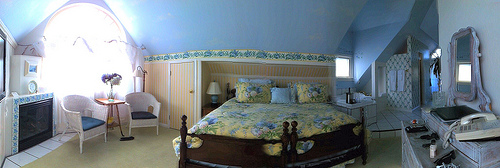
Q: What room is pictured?
A: It is a bedroom.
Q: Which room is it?
A: It is a bedroom.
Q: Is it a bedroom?
A: Yes, it is a bedroom.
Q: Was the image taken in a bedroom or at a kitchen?
A: It was taken at a bedroom.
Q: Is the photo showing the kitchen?
A: No, the picture is showing the bedroom.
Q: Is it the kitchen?
A: No, it is the bedroom.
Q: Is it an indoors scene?
A: Yes, it is indoors.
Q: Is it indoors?
A: Yes, it is indoors.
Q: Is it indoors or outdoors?
A: It is indoors.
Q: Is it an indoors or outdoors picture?
A: It is indoors.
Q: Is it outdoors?
A: No, it is indoors.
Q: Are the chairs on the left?
A: Yes, the chairs are on the left of the image.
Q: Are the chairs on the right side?
A: No, the chairs are on the left of the image.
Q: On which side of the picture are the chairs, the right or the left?
A: The chairs are on the left of the image.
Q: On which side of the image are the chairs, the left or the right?
A: The chairs are on the left of the image.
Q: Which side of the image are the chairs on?
A: The chairs are on the left of the image.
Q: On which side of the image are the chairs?
A: The chairs are on the left of the image.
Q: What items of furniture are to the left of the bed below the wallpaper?
A: The pieces of furniture are chairs.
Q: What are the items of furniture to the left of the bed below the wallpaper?
A: The pieces of furniture are chairs.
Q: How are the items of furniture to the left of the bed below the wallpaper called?
A: The pieces of furniture are chairs.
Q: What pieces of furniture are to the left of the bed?
A: The pieces of furniture are chairs.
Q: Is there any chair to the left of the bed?
A: Yes, there are chairs to the left of the bed.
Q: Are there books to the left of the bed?
A: No, there are chairs to the left of the bed.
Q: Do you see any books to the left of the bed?
A: No, there are chairs to the left of the bed.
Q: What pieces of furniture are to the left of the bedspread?
A: The pieces of furniture are chairs.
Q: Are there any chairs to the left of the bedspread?
A: Yes, there are chairs to the left of the bedspread.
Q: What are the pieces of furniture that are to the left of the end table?
A: The pieces of furniture are chairs.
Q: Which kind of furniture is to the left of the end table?
A: The pieces of furniture are chairs.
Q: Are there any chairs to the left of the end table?
A: Yes, there are chairs to the left of the end table.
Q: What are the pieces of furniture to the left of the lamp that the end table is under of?
A: The pieces of furniture are chairs.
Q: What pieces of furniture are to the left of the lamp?
A: The pieces of furniture are chairs.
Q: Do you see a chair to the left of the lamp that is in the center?
A: Yes, there are chairs to the left of the lamp.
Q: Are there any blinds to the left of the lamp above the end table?
A: No, there are chairs to the left of the lamp.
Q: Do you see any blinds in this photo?
A: No, there are no blinds.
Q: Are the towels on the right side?
A: Yes, the towels are on the right of the image.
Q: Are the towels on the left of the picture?
A: No, the towels are on the right of the image.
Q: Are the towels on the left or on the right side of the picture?
A: The towels are on the right of the image.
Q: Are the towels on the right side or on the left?
A: The towels are on the right of the image.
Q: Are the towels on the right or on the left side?
A: The towels are on the right of the image.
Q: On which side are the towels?
A: The towels are on the right of the image.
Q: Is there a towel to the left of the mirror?
A: Yes, there are towels to the left of the mirror.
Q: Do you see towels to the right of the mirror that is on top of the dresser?
A: No, the towels are to the left of the mirror.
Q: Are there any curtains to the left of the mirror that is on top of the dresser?
A: No, there are towels to the left of the mirror.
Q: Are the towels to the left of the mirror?
A: Yes, the towels are to the left of the mirror.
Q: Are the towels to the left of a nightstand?
A: No, the towels are to the left of the mirror.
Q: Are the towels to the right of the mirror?
A: No, the towels are to the left of the mirror.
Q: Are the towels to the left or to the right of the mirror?
A: The towels are to the left of the mirror.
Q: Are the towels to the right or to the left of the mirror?
A: The towels are to the left of the mirror.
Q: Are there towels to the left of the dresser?
A: Yes, there are towels to the left of the dresser.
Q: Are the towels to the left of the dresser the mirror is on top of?
A: Yes, the towels are to the left of the dresser.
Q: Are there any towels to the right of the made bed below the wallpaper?
A: Yes, there are towels to the right of the bed.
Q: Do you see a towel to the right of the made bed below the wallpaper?
A: Yes, there are towels to the right of the bed.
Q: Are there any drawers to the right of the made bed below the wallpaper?
A: No, there are towels to the right of the bed.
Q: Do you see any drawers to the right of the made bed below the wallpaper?
A: No, there are towels to the right of the bed.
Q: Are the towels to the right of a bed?
A: Yes, the towels are to the right of a bed.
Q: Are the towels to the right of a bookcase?
A: No, the towels are to the right of a bed.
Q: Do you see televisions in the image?
A: No, there are no televisions.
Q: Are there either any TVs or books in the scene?
A: No, there are no TVs or books.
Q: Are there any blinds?
A: No, there are no blinds.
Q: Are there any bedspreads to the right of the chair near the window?
A: Yes, there is a bedspread to the right of the chair.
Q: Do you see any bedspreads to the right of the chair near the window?
A: Yes, there is a bedspread to the right of the chair.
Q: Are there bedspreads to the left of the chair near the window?
A: No, the bedspread is to the right of the chair.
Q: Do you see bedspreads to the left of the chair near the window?
A: No, the bedspread is to the right of the chair.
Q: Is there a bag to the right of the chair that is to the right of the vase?
A: No, there is a bedspread to the right of the chair.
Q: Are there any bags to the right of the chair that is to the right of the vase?
A: No, there is a bedspread to the right of the chair.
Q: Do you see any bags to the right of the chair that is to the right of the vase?
A: No, there is a bedspread to the right of the chair.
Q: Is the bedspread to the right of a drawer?
A: No, the bedspread is to the right of the chair.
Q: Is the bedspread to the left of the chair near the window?
A: No, the bedspread is to the right of the chair.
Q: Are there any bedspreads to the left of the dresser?
A: Yes, there is a bedspread to the left of the dresser.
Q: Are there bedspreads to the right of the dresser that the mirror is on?
A: No, the bedspread is to the left of the dresser.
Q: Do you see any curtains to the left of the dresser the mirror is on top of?
A: No, there is a bedspread to the left of the dresser.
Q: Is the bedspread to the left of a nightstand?
A: No, the bedspread is to the left of a dresser.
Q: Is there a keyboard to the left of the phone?
A: No, there is a bedspread to the left of the phone.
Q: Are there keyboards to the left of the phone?
A: No, there is a bedspread to the left of the phone.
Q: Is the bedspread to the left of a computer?
A: No, the bedspread is to the left of the phone.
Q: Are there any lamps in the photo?
A: Yes, there is a lamp.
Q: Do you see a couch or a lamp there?
A: Yes, there is a lamp.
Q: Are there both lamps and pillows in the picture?
A: Yes, there are both a lamp and a pillow.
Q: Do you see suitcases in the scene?
A: No, there are no suitcases.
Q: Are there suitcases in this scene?
A: No, there are no suitcases.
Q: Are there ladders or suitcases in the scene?
A: No, there are no suitcases or ladders.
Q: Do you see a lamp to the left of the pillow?
A: Yes, there is a lamp to the left of the pillow.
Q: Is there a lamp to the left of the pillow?
A: Yes, there is a lamp to the left of the pillow.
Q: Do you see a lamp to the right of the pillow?
A: No, the lamp is to the left of the pillow.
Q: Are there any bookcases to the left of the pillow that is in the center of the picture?
A: No, there is a lamp to the left of the pillow.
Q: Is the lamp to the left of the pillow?
A: Yes, the lamp is to the left of the pillow.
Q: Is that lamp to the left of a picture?
A: No, the lamp is to the left of the pillow.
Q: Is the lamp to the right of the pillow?
A: No, the lamp is to the left of the pillow.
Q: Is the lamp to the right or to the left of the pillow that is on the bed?
A: The lamp is to the left of the pillow.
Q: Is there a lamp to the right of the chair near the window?
A: Yes, there is a lamp to the right of the chair.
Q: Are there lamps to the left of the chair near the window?
A: No, the lamp is to the right of the chair.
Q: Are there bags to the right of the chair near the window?
A: No, there is a lamp to the right of the chair.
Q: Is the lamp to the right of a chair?
A: Yes, the lamp is to the right of a chair.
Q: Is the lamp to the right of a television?
A: No, the lamp is to the right of a chair.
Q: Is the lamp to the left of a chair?
A: No, the lamp is to the right of a chair.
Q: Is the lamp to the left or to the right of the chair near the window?
A: The lamp is to the right of the chair.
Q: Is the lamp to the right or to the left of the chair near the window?
A: The lamp is to the right of the chair.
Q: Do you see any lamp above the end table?
A: Yes, there is a lamp above the end table.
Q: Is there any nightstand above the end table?
A: No, there is a lamp above the end table.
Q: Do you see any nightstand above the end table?
A: No, there is a lamp above the end table.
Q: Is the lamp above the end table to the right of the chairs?
A: Yes, the lamp is above the end table.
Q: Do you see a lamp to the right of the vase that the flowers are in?
A: Yes, there is a lamp to the right of the vase.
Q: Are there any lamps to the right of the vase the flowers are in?
A: Yes, there is a lamp to the right of the vase.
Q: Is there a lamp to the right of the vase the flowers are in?
A: Yes, there is a lamp to the right of the vase.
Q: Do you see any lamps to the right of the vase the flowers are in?
A: Yes, there is a lamp to the right of the vase.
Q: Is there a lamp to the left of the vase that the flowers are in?
A: No, the lamp is to the right of the vase.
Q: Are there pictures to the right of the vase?
A: No, there is a lamp to the right of the vase.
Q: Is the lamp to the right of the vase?
A: Yes, the lamp is to the right of the vase.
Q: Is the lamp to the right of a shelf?
A: No, the lamp is to the right of the vase.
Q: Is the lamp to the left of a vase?
A: No, the lamp is to the right of a vase.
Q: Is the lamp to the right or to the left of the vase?
A: The lamp is to the right of the vase.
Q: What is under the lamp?
A: The end table is under the lamp.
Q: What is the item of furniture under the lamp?
A: The piece of furniture is an end table.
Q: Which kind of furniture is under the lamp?
A: The piece of furniture is an end table.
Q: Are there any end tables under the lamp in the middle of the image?
A: Yes, there is an end table under the lamp.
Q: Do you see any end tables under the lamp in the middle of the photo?
A: Yes, there is an end table under the lamp.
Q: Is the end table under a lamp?
A: Yes, the end table is under a lamp.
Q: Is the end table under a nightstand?
A: No, the end table is under a lamp.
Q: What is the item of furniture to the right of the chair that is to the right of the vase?
A: The piece of furniture is an end table.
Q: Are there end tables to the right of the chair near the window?
A: Yes, there is an end table to the right of the chair.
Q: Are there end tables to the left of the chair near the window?
A: No, the end table is to the right of the chair.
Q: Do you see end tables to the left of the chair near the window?
A: No, the end table is to the right of the chair.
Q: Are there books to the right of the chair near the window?
A: No, there is an end table to the right of the chair.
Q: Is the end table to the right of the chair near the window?
A: Yes, the end table is to the right of the chair.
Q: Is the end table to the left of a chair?
A: No, the end table is to the right of a chair.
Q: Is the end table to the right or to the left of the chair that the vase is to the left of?
A: The end table is to the right of the chair.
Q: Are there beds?
A: Yes, there is a bed.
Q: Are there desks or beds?
A: Yes, there is a bed.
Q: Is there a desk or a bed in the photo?
A: Yes, there is a bed.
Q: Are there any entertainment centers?
A: No, there are no entertainment centers.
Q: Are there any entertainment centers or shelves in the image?
A: No, there are no entertainment centers or shelves.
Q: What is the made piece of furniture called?
A: The piece of furniture is a bed.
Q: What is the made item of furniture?
A: The piece of furniture is a bed.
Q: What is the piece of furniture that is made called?
A: The piece of furniture is a bed.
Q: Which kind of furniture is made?
A: The furniture is a bed.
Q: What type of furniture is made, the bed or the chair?
A: The bed is made.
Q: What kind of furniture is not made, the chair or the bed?
A: The chair is not made.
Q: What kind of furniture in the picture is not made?
A: The furniture is a chair.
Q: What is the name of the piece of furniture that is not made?
A: The piece of furniture is a chair.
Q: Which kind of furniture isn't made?
A: The furniture is a chair.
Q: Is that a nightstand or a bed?
A: That is a bed.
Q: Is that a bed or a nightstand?
A: That is a bed.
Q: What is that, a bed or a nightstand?
A: That is a bed.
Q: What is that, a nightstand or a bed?
A: That is a bed.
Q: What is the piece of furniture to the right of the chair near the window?
A: The piece of furniture is a bed.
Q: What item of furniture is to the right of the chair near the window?
A: The piece of furniture is a bed.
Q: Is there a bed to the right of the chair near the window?
A: Yes, there is a bed to the right of the chair.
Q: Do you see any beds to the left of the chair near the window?
A: No, the bed is to the right of the chair.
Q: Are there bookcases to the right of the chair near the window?
A: No, there is a bed to the right of the chair.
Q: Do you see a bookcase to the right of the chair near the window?
A: No, there is a bed to the right of the chair.